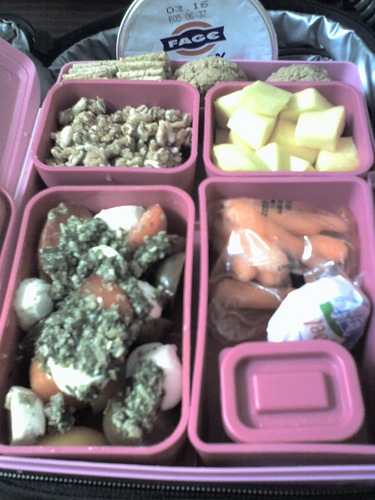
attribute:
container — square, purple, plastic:
[201, 82, 374, 178]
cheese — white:
[215, 79, 361, 169]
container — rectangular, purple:
[1, 184, 196, 457]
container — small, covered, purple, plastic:
[220, 342, 370, 443]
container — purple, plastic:
[186, 175, 374, 469]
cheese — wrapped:
[266, 275, 372, 352]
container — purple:
[31, 80, 202, 188]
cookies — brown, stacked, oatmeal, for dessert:
[172, 57, 334, 106]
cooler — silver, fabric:
[0, 3, 373, 500]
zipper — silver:
[1, 470, 374, 499]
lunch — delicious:
[1, 0, 370, 446]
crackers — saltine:
[60, 51, 170, 80]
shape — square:
[251, 371, 334, 416]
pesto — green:
[34, 293, 123, 374]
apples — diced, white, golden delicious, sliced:
[213, 81, 360, 172]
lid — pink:
[0, 38, 40, 197]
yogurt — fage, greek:
[116, 1, 278, 61]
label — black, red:
[160, 19, 227, 58]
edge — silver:
[1, 12, 372, 106]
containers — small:
[29, 78, 374, 186]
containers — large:
[3, 176, 374, 467]